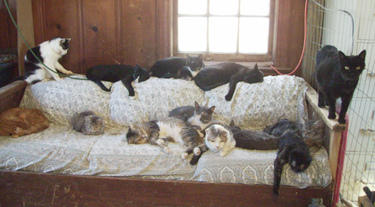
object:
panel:
[0, 171, 333, 206]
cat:
[266, 119, 313, 197]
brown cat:
[0, 108, 49, 138]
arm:
[339, 95, 352, 119]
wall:
[0, 0, 375, 207]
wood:
[0, 0, 303, 80]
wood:
[0, 170, 331, 207]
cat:
[228, 119, 277, 149]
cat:
[10, 37, 73, 85]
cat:
[193, 61, 264, 101]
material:
[49, 137, 139, 167]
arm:
[329, 96, 335, 115]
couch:
[0, 74, 347, 207]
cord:
[4, 0, 89, 81]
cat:
[71, 111, 105, 136]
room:
[0, 0, 375, 207]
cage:
[328, 126, 375, 203]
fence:
[302, 0, 375, 207]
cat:
[86, 63, 152, 99]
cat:
[315, 45, 365, 124]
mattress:
[0, 74, 332, 189]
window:
[175, 0, 270, 55]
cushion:
[0, 75, 333, 190]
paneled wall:
[0, 0, 304, 78]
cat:
[149, 54, 203, 79]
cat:
[190, 123, 236, 166]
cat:
[169, 100, 216, 130]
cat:
[126, 117, 205, 159]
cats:
[301, 117, 325, 147]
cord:
[269, 0, 308, 75]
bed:
[0, 77, 348, 206]